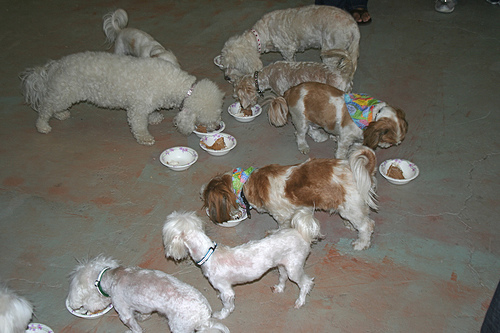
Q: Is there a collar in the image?
A: Yes, there is a collar.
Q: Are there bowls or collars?
A: Yes, there is a collar.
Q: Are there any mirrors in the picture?
A: No, there are no mirrors.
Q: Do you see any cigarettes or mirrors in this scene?
A: No, there are no mirrors or cigarettes.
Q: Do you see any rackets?
A: No, there are no rackets.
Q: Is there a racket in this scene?
A: No, there are no rackets.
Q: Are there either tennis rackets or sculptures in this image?
A: No, there are no tennis rackets or sculptures.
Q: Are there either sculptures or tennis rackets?
A: No, there are no tennis rackets or sculptures.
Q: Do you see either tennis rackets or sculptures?
A: No, there are no tennis rackets or sculptures.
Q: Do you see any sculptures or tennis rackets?
A: No, there are no tennis rackets or sculptures.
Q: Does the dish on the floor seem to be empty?
A: Yes, the dish is empty.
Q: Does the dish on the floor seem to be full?
A: No, the dish is empty.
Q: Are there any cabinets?
A: No, there are no cabinets.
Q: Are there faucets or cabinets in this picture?
A: No, there are no cabinets or faucets.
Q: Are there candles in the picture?
A: No, there are no candles.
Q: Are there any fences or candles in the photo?
A: No, there are no candles or fences.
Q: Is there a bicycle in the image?
A: No, there are no bicycles.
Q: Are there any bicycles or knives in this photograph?
A: No, there are no bicycles or knives.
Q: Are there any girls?
A: No, there are no girls.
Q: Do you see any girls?
A: No, there are no girls.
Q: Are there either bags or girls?
A: No, there are no girls or bags.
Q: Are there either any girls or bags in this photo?
A: No, there are no girls or bags.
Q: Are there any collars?
A: Yes, there is a collar.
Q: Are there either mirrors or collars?
A: Yes, there is a collar.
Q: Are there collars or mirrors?
A: Yes, there is a collar.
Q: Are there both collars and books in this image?
A: No, there is a collar but no books.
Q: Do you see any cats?
A: No, there are no cats.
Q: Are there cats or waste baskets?
A: No, there are no cats or waste baskets.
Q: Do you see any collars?
A: Yes, there is a collar.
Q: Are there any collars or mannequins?
A: Yes, there is a collar.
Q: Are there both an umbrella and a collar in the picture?
A: No, there is a collar but no umbrellas.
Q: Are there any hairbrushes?
A: No, there are no hairbrushes.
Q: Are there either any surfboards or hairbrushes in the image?
A: No, there are no hairbrushes or surfboards.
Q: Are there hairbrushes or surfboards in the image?
A: No, there are no hairbrushes or surfboards.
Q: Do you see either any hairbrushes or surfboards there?
A: No, there are no hairbrushes or surfboards.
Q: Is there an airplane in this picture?
A: No, there are no airplanes.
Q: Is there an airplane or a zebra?
A: No, there are no airplanes or zebras.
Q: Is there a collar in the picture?
A: Yes, there is a collar.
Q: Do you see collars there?
A: Yes, there is a collar.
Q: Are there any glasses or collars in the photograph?
A: Yes, there is a collar.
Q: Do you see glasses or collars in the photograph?
A: Yes, there is a collar.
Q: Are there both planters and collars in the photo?
A: No, there is a collar but no planters.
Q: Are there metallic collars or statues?
A: Yes, there is a metal collar.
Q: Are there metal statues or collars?
A: Yes, there is a metal collar.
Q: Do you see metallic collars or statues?
A: Yes, there is a metal collar.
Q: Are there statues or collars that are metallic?
A: Yes, the collar is metallic.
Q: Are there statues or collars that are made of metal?
A: Yes, the collar is made of metal.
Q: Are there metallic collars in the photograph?
A: Yes, there is a metal collar.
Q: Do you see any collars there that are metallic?
A: Yes, there is a collar that is metallic.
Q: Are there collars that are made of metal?
A: Yes, there is a collar that is made of metal.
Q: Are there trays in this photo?
A: No, there are no trays.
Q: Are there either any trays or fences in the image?
A: No, there are no trays or fences.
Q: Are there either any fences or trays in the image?
A: No, there are no trays or fences.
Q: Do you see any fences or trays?
A: No, there are no trays or fences.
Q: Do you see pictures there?
A: No, there are no pictures.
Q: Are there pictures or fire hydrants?
A: No, there are no pictures or fire hydrants.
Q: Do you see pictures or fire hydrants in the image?
A: No, there are no pictures or fire hydrants.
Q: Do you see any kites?
A: No, there are no kites.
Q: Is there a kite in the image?
A: No, there are no kites.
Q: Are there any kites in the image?
A: No, there are no kites.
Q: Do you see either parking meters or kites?
A: No, there are no kites or parking meters.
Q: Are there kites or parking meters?
A: No, there are no kites or parking meters.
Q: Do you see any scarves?
A: Yes, there is a scarf.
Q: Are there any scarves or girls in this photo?
A: Yes, there is a scarf.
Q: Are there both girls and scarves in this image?
A: No, there is a scarf but no girls.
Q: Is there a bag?
A: No, there are no bags.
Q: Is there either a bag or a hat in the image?
A: No, there are no bags or hats.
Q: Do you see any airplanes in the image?
A: No, there are no airplanes.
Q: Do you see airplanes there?
A: No, there are no airplanes.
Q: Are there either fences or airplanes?
A: No, there are no airplanes or fences.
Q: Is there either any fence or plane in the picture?
A: No, there are no airplanes or fences.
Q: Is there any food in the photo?
A: Yes, there is food.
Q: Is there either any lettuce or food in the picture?
A: Yes, there is food.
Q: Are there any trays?
A: No, there are no trays.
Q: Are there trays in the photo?
A: No, there are no trays.